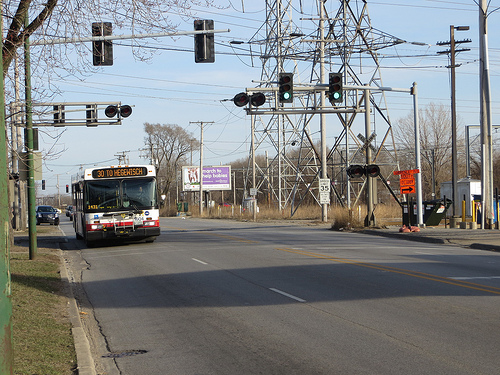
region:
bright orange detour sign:
[387, 159, 427, 223]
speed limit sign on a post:
[302, 167, 339, 231]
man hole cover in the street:
[99, 334, 159, 372]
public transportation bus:
[76, 159, 171, 248]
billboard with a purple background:
[176, 161, 241, 200]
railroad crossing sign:
[348, 130, 386, 157]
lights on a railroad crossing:
[340, 161, 386, 195]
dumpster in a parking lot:
[392, 200, 454, 232]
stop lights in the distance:
[38, 178, 74, 205]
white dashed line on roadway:
[180, 244, 317, 339]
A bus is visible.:
[63, 127, 189, 250]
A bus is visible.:
[0, 93, 175, 232]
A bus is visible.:
[16, 46, 141, 183]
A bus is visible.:
[89, 101, 159, 259]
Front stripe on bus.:
[86, 221, 221, 245]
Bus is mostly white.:
[68, 146, 257, 350]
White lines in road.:
[161, 212, 293, 362]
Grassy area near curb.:
[13, 264, 64, 365]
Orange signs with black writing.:
[377, 156, 477, 281]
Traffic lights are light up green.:
[276, 83, 366, 123]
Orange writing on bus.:
[92, 158, 214, 216]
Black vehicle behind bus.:
[25, 200, 87, 259]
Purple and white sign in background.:
[160, 163, 356, 239]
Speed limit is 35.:
[323, 178, 329, 199]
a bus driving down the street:
[44, 150, 166, 260]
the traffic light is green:
[225, 53, 370, 130]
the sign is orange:
[362, 155, 437, 210]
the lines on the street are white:
[149, 239, 352, 340]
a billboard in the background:
[150, 145, 244, 200]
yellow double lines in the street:
[314, 247, 489, 298]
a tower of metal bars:
[226, 4, 401, 251]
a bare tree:
[3, 0, 181, 97]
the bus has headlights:
[82, 215, 169, 257]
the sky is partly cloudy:
[75, 62, 315, 149]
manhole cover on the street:
[96, 340, 158, 360]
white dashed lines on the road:
[191, 254, 321, 314]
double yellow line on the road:
[301, 235, 432, 292]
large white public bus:
[69, 156, 175, 244]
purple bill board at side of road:
[183, 165, 230, 199]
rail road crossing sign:
[341, 132, 386, 199]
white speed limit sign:
[313, 172, 342, 227]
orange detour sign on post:
[394, 161, 420, 197]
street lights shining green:
[271, 60, 361, 115]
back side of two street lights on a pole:
[83, 15, 233, 80]